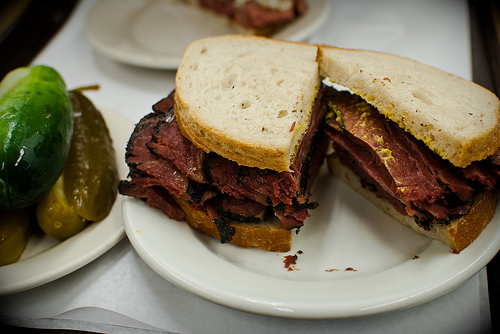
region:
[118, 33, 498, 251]
a smoked meat with mustard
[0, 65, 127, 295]
pickles on a white plate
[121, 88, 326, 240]
smoked meat inside a sandwich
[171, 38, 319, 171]
a half loaf of bread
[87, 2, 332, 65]
a half empty white plate on a table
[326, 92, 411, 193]
mustard on smoked meat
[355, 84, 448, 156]
mustard on the side of a loaf of bread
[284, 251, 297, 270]
bit of meat on a white plate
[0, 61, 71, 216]
a green pickle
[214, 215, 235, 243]
a burned bit of meat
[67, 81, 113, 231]
pickle on a plate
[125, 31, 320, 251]
half of sandwich on plate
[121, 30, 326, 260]
half of sandwich on white plate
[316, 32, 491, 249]
half of sandwich on plate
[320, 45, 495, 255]
half of sandwich on white plate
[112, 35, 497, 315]
sandwich on the plate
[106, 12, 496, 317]
sandwich on the white plate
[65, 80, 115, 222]
pickle next to the sandwich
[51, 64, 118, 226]
pickle in a stack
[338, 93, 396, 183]
mustard on the sandwich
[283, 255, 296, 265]
SAUCE ON THE PLATE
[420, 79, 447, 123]
BREAD MADE OUT OF WHEAT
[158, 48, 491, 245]
SANDWICH CUT IN HALF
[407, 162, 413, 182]
ROAST BEEF ON THE BREAD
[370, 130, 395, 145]
MUSTARD ON THE MEAT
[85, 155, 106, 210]
PICKLES ON THE PLATE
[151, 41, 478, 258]
white bread for sandwich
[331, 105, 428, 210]
yellow mustard on ham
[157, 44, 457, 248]
sandwich split in half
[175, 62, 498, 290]
sandwich on white plate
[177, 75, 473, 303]
white plate on white table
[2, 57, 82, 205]
green cucumber on plate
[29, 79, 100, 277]
dark green pickles under cucumber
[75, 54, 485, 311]
plate on parchment paper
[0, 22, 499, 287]
A roast beef sandwich with pickles on the side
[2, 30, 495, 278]
A roast beef sandwich with pickles on the side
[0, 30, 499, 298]
A roast beef sandwich with pickles on the side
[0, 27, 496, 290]
A roast beef sandwich with pickles on the side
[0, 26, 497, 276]
A roast beef sandwich with pickles on the side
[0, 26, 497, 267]
A roast beef sandwich with pickles on the side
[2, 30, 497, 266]
A roast beef sandwich with pickles on the side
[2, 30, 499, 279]
A roast beef sandwich with pickles on the side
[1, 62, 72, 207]
the pickle is green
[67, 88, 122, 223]
the dark green pickle on the plate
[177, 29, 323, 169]
the slice of bread on the sandwich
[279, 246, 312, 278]
the sauce on the plate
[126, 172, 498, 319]
the plate is holding the sandwich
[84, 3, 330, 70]
the plate behind the sandwich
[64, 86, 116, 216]
pickle is on a plate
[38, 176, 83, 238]
pickle is on a plate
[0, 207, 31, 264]
pickle is on a plate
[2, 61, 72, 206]
pickle is on a plate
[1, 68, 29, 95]
pickle is on a plate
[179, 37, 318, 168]
white bread is sliced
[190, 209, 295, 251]
white bread is sliced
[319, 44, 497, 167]
white bread is sliced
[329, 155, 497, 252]
white bread is sliced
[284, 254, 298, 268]
crumb is on the plate